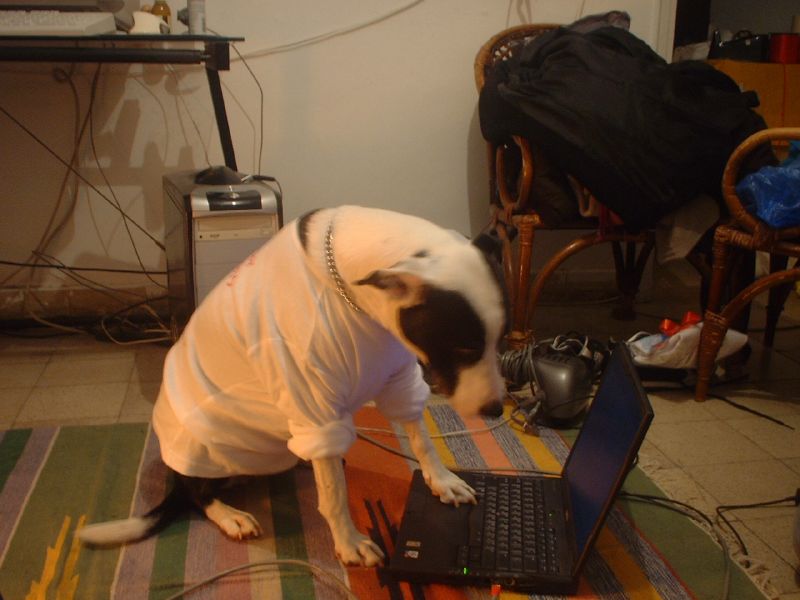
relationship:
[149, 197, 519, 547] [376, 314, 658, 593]
dog touching laptop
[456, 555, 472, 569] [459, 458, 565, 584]
button on keyboard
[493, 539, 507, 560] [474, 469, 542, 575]
button on keyboard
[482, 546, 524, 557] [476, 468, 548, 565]
button on keyboard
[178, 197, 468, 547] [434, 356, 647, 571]
dog looking at laptop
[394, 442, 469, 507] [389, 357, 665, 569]
paw on a laptop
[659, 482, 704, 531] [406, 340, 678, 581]
cords of computer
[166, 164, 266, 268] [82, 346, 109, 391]
case on the floor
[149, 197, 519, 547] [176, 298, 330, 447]
dog wearing shirt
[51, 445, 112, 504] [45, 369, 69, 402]
rug over floor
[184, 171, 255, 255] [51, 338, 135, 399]
drive sitting on floor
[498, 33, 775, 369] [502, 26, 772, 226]
chairs covered miscellaneous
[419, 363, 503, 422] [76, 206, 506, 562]
mouth on dog